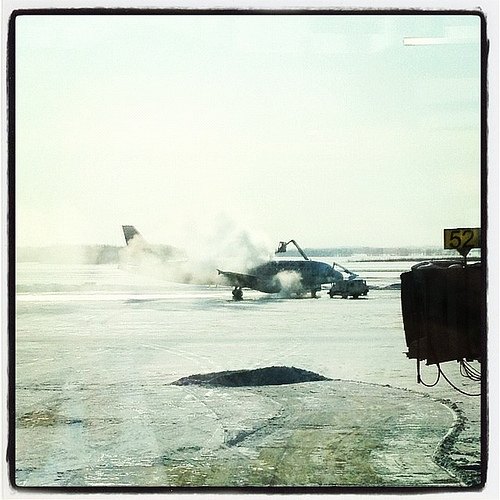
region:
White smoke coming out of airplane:
[166, 228, 239, 283]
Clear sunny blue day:
[127, 61, 274, 154]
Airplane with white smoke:
[129, 220, 360, 300]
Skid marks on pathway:
[86, 380, 220, 475]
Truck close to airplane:
[317, 261, 372, 306]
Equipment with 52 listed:
[395, 206, 498, 418]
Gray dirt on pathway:
[187, 358, 321, 399]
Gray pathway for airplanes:
[47, 309, 124, 398]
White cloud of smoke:
[207, 224, 260, 262]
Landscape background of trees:
[357, 244, 406, 269]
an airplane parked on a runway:
[116, 223, 343, 303]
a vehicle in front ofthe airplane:
[328, 276, 373, 301]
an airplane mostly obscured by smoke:
[114, 218, 343, 303]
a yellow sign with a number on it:
[440, 225, 482, 252]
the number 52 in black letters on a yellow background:
[442, 227, 480, 252]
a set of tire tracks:
[167, 358, 481, 490]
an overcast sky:
[15, 16, 488, 248]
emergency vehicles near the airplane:
[327, 276, 372, 303]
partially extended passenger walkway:
[395, 255, 482, 398]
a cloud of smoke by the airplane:
[114, 218, 307, 300]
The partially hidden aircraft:
[120, 209, 367, 304]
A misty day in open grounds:
[9, 14, 488, 489]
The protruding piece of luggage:
[400, 259, 487, 395]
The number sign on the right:
[442, 222, 487, 252]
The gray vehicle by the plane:
[332, 274, 369, 301]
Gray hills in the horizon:
[279, 247, 488, 260]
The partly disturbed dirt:
[14, 351, 481, 489]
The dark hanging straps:
[417, 357, 484, 395]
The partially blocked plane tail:
[119, 225, 151, 255]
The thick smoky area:
[276, 272, 301, 297]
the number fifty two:
[440, 215, 480, 260]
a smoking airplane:
[120, 208, 366, 310]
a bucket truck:
[315, 262, 370, 302]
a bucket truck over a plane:
[191, 231, 311, 310]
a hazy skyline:
[38, 153, 438, 259]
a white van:
[330, 277, 369, 304]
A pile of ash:
[167, 355, 345, 402]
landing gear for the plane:
[215, 267, 254, 309]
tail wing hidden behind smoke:
[116, 210, 184, 290]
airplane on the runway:
[123, 223, 343, 301]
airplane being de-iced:
[122, 228, 369, 300]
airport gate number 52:
[402, 228, 492, 392]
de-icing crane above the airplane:
[274, 238, 306, 258]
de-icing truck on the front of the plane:
[330, 263, 368, 299]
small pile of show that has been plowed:
[167, 366, 328, 383]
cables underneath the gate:
[415, 359, 481, 397]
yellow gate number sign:
[447, 223, 482, 248]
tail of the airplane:
[123, 225, 149, 271]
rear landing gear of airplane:
[231, 281, 244, 301]